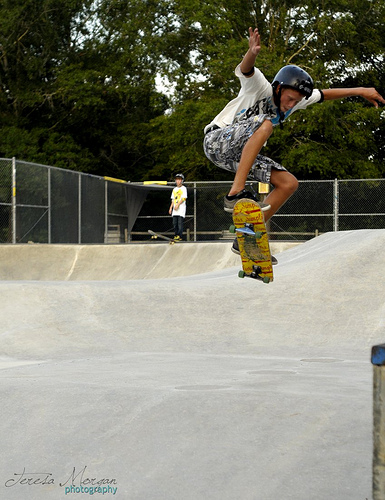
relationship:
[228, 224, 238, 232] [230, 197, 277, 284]
wheel on skateboard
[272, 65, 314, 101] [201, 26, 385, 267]
helmet on boy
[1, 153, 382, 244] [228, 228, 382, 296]
fence near ramp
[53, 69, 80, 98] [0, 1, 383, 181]
leaves on tree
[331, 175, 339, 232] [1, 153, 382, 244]
post on fence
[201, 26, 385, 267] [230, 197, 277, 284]
boy near skateboard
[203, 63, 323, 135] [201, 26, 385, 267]
shirt on boy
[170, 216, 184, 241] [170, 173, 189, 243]
jeans on skater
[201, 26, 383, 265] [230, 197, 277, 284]
boy on skateboard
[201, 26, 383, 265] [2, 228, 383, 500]
boy at skatepark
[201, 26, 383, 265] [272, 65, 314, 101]
boy wearing helmet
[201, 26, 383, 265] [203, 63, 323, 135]
boy wearing shirt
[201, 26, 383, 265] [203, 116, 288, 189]
boy wearing shorts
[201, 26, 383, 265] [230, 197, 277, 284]
boy has skateboard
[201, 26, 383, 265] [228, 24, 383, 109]
boy has arms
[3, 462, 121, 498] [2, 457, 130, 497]
name printed in corner